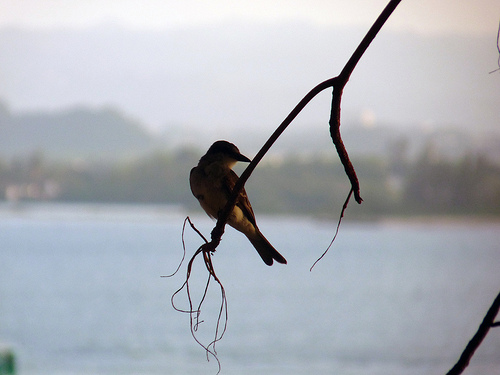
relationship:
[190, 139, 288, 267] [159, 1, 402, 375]
bird sitting on branch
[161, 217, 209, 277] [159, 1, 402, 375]
twig on branch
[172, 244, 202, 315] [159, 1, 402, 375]
twig on branch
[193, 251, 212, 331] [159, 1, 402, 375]
twig on branch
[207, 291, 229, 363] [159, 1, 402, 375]
twig on branch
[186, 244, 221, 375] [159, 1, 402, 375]
twig on branch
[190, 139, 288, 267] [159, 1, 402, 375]
bird on branch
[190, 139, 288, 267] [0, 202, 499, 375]
bird near water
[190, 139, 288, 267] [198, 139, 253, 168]
bird has head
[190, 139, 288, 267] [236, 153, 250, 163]
bird has beak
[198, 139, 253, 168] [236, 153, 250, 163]
head has beak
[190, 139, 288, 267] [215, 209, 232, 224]
bird has feet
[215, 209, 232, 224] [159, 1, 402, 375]
feet grip branch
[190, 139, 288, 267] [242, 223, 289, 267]
bird has tail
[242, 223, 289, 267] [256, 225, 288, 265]
tail has feather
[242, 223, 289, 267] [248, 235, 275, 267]
tail has feather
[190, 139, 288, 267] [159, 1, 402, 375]
bird resting on branch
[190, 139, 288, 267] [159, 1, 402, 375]
bird gripping branch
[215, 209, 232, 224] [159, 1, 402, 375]
feet gripping branch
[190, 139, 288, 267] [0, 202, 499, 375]
bird overlooking water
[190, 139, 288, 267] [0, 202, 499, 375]
bird in front of water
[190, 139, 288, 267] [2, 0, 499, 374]
bird in front of background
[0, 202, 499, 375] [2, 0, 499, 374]
water in background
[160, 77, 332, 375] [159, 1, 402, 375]
twig attached to branch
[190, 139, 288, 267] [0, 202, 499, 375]
bird over water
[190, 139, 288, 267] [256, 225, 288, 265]
bird has feather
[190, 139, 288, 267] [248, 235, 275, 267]
bird has feather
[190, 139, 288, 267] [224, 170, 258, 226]
bird has wing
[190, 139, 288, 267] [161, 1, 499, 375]
bird on tree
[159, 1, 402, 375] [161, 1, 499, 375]
branch on tree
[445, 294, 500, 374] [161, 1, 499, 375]
branch on tree